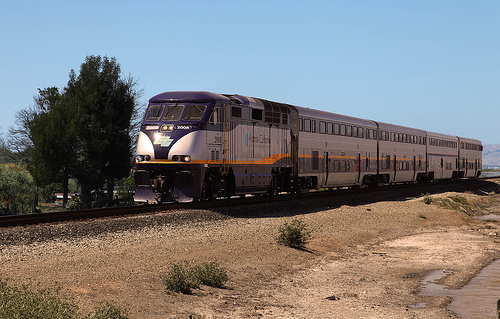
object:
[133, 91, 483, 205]
train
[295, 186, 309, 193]
wheel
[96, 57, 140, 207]
tree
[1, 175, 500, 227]
track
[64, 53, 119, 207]
tree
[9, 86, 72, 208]
tree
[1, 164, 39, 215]
tree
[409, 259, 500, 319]
water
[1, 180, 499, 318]
ground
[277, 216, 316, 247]
bush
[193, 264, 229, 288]
bush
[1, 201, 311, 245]
gravel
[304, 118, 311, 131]
window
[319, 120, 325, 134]
window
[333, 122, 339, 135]
window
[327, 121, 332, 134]
window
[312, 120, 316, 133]
window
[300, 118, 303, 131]
window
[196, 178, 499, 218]
shadow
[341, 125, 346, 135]
window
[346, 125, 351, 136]
window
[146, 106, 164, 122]
window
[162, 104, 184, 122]
window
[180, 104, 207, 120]
window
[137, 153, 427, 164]
stripe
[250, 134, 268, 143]
letters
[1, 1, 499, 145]
sky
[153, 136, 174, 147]
letters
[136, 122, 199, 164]
front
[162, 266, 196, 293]
bush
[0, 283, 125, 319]
bush